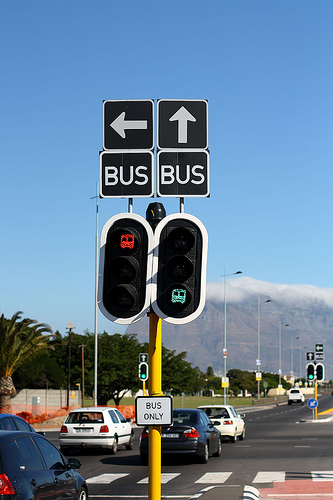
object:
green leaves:
[12, 319, 19, 345]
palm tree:
[0, 309, 56, 393]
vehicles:
[0, 388, 322, 496]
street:
[26, 385, 329, 497]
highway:
[81, 390, 328, 498]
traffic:
[0, 408, 132, 497]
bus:
[104, 162, 149, 189]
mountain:
[123, 279, 333, 378]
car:
[139, 408, 222, 461]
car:
[197, 404, 244, 441]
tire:
[231, 434, 237, 442]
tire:
[202, 444, 208, 464]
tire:
[109, 440, 118, 453]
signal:
[118, 234, 135, 250]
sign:
[103, 102, 152, 150]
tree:
[11, 329, 199, 392]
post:
[141, 312, 168, 498]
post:
[223, 264, 227, 408]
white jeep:
[282, 385, 311, 404]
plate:
[74, 428, 93, 433]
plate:
[162, 432, 181, 439]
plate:
[211, 420, 219, 423]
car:
[54, 398, 139, 459]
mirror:
[67, 459, 81, 470]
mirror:
[215, 421, 220, 425]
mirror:
[240, 413, 246, 418]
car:
[0, 430, 88, 498]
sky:
[0, 0, 331, 102]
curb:
[31, 426, 60, 432]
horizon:
[147, 343, 332, 392]